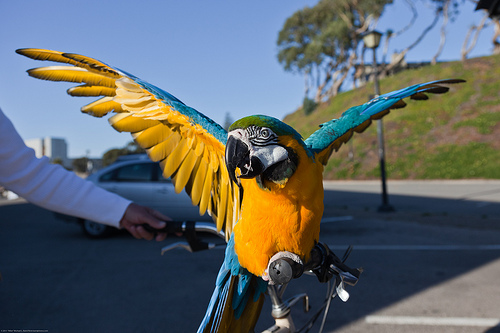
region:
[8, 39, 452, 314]
blue and yellow parrot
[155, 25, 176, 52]
white clouds in blue sky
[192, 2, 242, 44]
white clouds in blue sky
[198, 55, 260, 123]
white clouds in blue sky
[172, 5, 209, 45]
white clouds in blue sky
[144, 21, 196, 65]
white clouds in blue sky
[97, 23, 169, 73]
white clouds in blue sky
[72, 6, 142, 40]
white clouds in blue sky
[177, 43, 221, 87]
white clouds in blue sky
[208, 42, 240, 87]
white clouds in blue sky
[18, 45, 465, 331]
a blue and gold macaw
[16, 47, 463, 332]
a macaw on bike handles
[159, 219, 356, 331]
handlebars of a bicycle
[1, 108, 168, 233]
a person's left arm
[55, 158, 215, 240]
a silver car behind the macaw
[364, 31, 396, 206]
a black lamppost behind the macaw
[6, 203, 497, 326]
a parking lot with white stripes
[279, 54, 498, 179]
a grass covered hill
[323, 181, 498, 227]
sidewalk at the bottom of the hill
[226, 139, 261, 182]
the macaw's black beak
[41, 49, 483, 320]
bird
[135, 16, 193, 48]
white clouds in blue sky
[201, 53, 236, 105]
white clouds in blue sky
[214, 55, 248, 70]
white clouds in blue sky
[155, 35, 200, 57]
white clouds in blue sky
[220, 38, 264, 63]
white clouds in blue sky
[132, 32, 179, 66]
white clouds in blue sky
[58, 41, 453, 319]
yellow and blue aprrot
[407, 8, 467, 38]
white clouds in blue sky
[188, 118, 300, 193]
face of the parrot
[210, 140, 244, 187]
mouth of the parrot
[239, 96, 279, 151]
eye of the parrot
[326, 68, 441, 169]
right wing of parrot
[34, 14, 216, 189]
left wing of parrot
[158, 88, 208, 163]
skin of the parrot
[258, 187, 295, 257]
yellow skin of parrot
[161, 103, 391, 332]
a parrot on cycle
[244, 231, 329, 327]
handle of the cycle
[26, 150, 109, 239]
hand of the person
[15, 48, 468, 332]
An orange and blue parrot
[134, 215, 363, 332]
A bike handle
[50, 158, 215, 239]
A car in a parking lot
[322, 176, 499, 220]
A paved sidewalk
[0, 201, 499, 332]
A parking lot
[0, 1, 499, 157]
A clear blue sky above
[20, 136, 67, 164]
A white building in the distance.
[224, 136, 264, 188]
Large black beak of bird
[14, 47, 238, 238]
Long wing of parrot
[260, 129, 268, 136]
Eye of the parrot